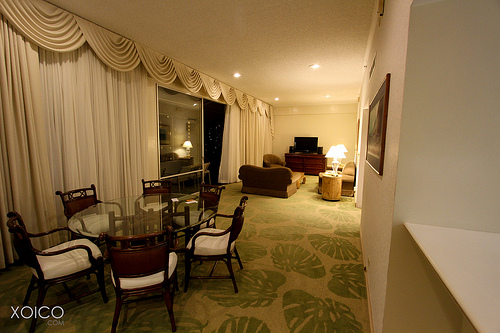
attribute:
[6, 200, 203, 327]
chairs — white, brown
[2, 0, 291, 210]
curtain — white, big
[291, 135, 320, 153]
tv — off, flat screen, black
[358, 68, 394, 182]
picture — brown, black, hanging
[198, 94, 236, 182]
window — open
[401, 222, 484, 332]
counter — white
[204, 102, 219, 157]
sky — black, night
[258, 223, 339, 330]
pattern — green leaf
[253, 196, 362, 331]
carpet — green, beige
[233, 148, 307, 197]
sofa — brown, camel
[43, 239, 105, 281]
cushion — white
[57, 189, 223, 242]
table — glass top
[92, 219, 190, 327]
chair — wooden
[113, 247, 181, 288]
seat — white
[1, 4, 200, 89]
valance — beige, festooned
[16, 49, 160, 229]
curtains — beige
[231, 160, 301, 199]
couch — greenish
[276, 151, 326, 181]
drawers — maple wood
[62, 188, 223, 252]
table — round, clear, large, glass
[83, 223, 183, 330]
chair — burgundy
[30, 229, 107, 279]
cushion — white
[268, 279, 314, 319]
carpet — teal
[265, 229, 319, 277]
design — green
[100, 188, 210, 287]
top — round, glass